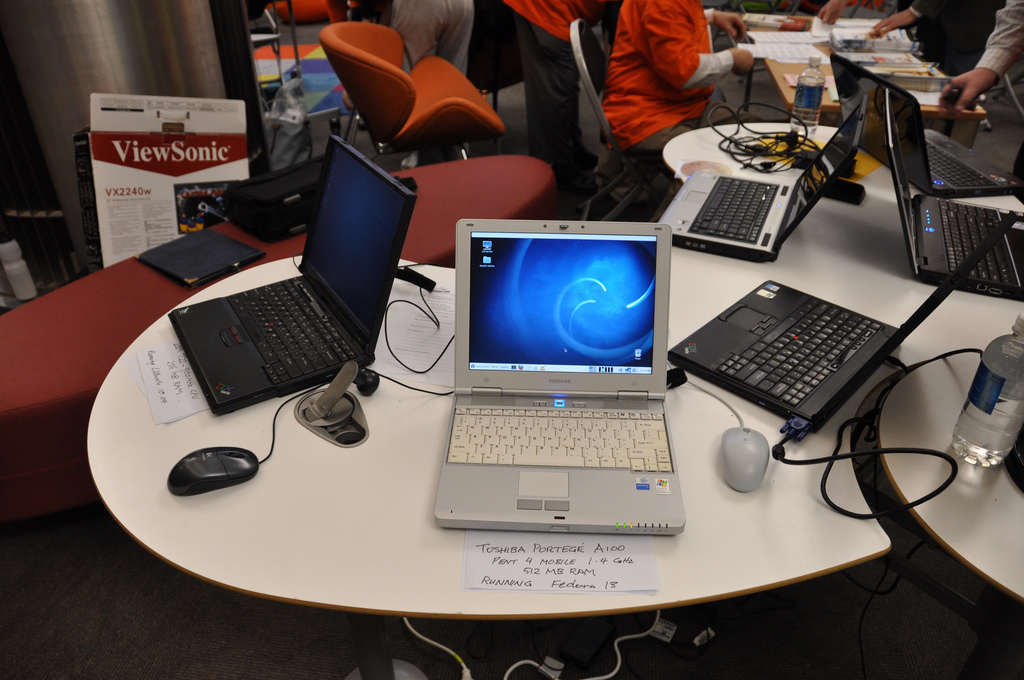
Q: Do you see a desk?
A: Yes, there is a desk.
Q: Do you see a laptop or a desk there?
A: Yes, there is a desk.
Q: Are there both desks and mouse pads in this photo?
A: No, there is a desk but no mouse pads.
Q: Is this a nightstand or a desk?
A: This is a desk.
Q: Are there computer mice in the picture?
A: Yes, there is a computer mouse.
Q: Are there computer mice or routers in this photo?
A: Yes, there is a computer mouse.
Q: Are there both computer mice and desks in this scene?
A: Yes, there are both a computer mouse and a desk.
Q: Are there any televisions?
A: No, there are no televisions.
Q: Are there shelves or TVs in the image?
A: No, there are no TVs or shelves.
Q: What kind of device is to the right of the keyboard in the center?
A: The device is a computer mouse.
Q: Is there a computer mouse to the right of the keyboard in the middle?
A: Yes, there is a computer mouse to the right of the keyboard.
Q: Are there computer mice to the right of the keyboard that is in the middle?
A: Yes, there is a computer mouse to the right of the keyboard.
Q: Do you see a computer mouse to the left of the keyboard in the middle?
A: No, the computer mouse is to the right of the keyboard.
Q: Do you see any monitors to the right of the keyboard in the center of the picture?
A: No, there is a computer mouse to the right of the keyboard.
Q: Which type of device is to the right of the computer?
A: The device is a computer mouse.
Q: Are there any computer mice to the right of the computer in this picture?
A: Yes, there is a computer mouse to the right of the computer.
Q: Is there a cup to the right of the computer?
A: No, there is a computer mouse to the right of the computer.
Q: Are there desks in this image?
A: Yes, there is a desk.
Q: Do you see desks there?
A: Yes, there is a desk.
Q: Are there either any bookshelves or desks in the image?
A: Yes, there is a desk.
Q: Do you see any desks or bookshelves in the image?
A: Yes, there is a desk.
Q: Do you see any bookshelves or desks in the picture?
A: Yes, there is a desk.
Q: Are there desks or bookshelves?
A: Yes, there is a desk.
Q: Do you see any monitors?
A: No, there are no monitors.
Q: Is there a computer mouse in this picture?
A: Yes, there is a computer mouse.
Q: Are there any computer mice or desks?
A: Yes, there is a computer mouse.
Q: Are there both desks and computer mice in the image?
A: Yes, there are both a computer mouse and a desk.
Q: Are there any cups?
A: No, there are no cups.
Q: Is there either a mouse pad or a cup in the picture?
A: No, there are no cups or mouse pads.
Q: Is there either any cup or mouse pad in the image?
A: No, there are no cups or mouse pads.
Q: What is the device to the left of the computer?
A: The device is a computer mouse.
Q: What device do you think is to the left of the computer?
A: The device is a computer mouse.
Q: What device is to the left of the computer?
A: The device is a computer mouse.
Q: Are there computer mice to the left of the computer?
A: Yes, there is a computer mouse to the left of the computer.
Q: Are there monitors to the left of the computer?
A: No, there is a computer mouse to the left of the computer.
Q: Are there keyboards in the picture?
A: Yes, there is a keyboard.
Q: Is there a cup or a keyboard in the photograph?
A: Yes, there is a keyboard.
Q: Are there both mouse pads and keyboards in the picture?
A: No, there is a keyboard but no mouse pads.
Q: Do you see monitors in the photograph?
A: No, there are no monitors.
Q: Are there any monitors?
A: No, there are no monitors.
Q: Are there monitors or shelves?
A: No, there are no monitors or shelves.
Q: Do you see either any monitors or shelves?
A: No, there are no monitors or shelves.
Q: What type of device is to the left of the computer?
A: The device is a keyboard.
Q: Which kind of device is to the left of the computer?
A: The device is a keyboard.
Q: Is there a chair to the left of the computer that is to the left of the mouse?
A: No, there is a keyboard to the left of the computer.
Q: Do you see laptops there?
A: Yes, there is a laptop.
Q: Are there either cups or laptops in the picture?
A: Yes, there is a laptop.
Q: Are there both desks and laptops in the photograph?
A: Yes, there are both a laptop and a desk.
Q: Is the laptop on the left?
A: Yes, the laptop is on the left of the image.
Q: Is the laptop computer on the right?
A: No, the laptop computer is on the left of the image.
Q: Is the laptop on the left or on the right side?
A: The laptop is on the left of the image.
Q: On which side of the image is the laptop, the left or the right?
A: The laptop is on the left of the image.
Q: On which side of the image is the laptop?
A: The laptop is on the left of the image.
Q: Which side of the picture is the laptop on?
A: The laptop is on the left of the image.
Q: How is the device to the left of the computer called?
A: The device is a laptop.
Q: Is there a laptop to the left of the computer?
A: Yes, there is a laptop to the left of the computer.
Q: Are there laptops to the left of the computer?
A: Yes, there is a laptop to the left of the computer.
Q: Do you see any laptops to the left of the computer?
A: Yes, there is a laptop to the left of the computer.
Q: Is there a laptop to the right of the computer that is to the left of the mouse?
A: No, the laptop is to the left of the computer.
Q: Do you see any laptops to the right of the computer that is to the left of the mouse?
A: No, the laptop is to the left of the computer.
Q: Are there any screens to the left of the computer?
A: No, there is a laptop to the left of the computer.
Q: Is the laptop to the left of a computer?
A: Yes, the laptop is to the left of a computer.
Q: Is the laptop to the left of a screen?
A: No, the laptop is to the left of a computer.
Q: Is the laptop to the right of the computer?
A: No, the laptop is to the left of the computer.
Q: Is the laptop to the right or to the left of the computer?
A: The laptop is to the left of the computer.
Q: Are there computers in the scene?
A: Yes, there is a computer.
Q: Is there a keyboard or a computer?
A: Yes, there is a computer.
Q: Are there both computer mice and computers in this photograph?
A: Yes, there are both a computer and a computer mouse.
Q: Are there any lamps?
A: No, there are no lamps.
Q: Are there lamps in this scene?
A: No, there are no lamps.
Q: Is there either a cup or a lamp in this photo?
A: No, there are no lamps or cups.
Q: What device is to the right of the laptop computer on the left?
A: The device is a computer.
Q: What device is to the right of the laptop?
A: The device is a computer.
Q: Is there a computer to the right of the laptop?
A: Yes, there is a computer to the right of the laptop.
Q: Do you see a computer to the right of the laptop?
A: Yes, there is a computer to the right of the laptop.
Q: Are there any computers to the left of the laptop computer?
A: No, the computer is to the right of the laptop computer.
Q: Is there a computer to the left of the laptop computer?
A: No, the computer is to the right of the laptop computer.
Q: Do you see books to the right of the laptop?
A: No, there is a computer to the right of the laptop.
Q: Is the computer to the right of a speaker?
A: No, the computer is to the right of a laptop.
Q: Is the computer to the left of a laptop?
A: No, the computer is to the right of a laptop.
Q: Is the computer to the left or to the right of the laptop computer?
A: The computer is to the right of the laptop computer.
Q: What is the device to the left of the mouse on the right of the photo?
A: The device is a computer.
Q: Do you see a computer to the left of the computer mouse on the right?
A: Yes, there is a computer to the left of the mouse.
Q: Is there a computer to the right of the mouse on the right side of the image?
A: No, the computer is to the left of the computer mouse.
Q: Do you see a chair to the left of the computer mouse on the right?
A: No, there is a computer to the left of the computer mouse.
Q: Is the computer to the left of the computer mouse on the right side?
A: Yes, the computer is to the left of the mouse.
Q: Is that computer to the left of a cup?
A: No, the computer is to the left of the mouse.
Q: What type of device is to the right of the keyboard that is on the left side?
A: The device is a computer.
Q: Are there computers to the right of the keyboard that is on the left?
A: Yes, there is a computer to the right of the keyboard.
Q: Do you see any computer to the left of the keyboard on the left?
A: No, the computer is to the right of the keyboard.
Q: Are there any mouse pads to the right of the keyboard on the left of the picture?
A: No, there is a computer to the right of the keyboard.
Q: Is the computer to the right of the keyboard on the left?
A: Yes, the computer is to the right of the keyboard.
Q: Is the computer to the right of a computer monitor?
A: No, the computer is to the right of the keyboard.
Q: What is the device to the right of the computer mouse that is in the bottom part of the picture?
A: The device is a computer.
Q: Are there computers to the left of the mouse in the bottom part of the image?
A: No, the computer is to the right of the computer mouse.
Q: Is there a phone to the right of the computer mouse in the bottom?
A: No, there is a computer to the right of the computer mouse.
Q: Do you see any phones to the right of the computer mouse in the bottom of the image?
A: No, there is a computer to the right of the computer mouse.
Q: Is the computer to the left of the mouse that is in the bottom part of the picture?
A: No, the computer is to the right of the computer mouse.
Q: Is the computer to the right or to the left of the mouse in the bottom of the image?
A: The computer is to the right of the mouse.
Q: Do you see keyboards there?
A: Yes, there is a keyboard.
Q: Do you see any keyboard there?
A: Yes, there is a keyboard.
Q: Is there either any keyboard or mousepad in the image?
A: Yes, there is a keyboard.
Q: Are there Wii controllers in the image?
A: No, there are no Wii controllers.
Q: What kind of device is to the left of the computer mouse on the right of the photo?
A: The device is a keyboard.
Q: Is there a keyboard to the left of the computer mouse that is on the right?
A: Yes, there is a keyboard to the left of the mouse.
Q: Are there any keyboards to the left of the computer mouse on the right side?
A: Yes, there is a keyboard to the left of the mouse.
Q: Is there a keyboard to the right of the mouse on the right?
A: No, the keyboard is to the left of the mouse.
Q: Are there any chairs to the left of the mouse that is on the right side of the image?
A: No, there is a keyboard to the left of the mouse.